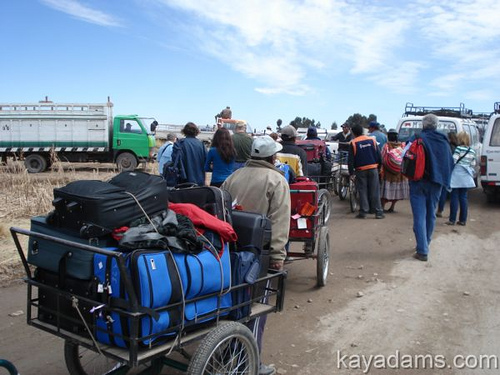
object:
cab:
[113, 116, 157, 162]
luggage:
[25, 169, 270, 349]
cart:
[10, 225, 288, 374]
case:
[93, 240, 234, 345]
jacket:
[219, 159, 293, 266]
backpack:
[402, 137, 426, 181]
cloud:
[38, 0, 129, 34]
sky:
[1, 0, 500, 132]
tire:
[185, 320, 262, 374]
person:
[446, 133, 477, 226]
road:
[261, 180, 500, 374]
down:
[126, 190, 186, 357]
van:
[396, 116, 483, 171]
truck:
[1, 97, 157, 173]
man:
[401, 114, 452, 261]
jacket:
[411, 133, 454, 187]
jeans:
[449, 188, 468, 223]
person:
[347, 125, 386, 216]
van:
[477, 103, 499, 203]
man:
[219, 135, 292, 278]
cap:
[251, 134, 283, 158]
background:
[2, 97, 499, 186]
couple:
[171, 122, 237, 189]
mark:
[335, 347, 500, 371]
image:
[0, 2, 499, 374]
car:
[398, 104, 481, 158]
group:
[394, 104, 499, 207]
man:
[106, 96, 115, 109]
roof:
[0, 103, 113, 117]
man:
[332, 122, 355, 165]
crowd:
[155, 112, 483, 283]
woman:
[164, 122, 208, 187]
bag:
[162, 157, 188, 187]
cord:
[194, 228, 225, 293]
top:
[453, 145, 477, 171]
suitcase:
[27, 213, 106, 278]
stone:
[358, 290, 364, 298]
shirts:
[170, 137, 235, 184]